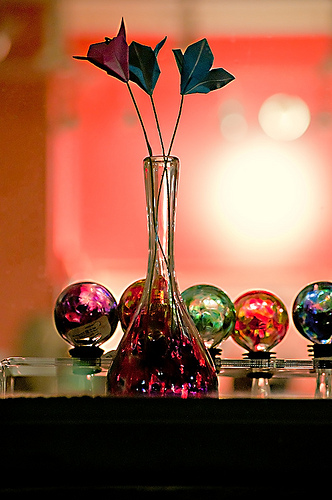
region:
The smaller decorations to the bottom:
[52, 265, 329, 352]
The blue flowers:
[136, 24, 228, 103]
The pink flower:
[73, 15, 138, 98]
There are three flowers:
[78, 14, 233, 103]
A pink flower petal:
[100, 36, 127, 81]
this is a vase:
[94, 141, 231, 411]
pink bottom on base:
[95, 305, 215, 409]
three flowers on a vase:
[60, 16, 253, 418]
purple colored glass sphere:
[46, 267, 124, 356]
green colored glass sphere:
[171, 270, 235, 362]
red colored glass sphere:
[231, 289, 291, 352]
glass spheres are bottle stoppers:
[17, 243, 330, 393]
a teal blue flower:
[163, 21, 247, 105]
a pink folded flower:
[77, 2, 136, 98]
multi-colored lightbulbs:
[51, 278, 330, 348]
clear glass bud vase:
[102, 151, 233, 391]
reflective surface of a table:
[11, 356, 331, 400]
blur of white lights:
[214, 96, 325, 265]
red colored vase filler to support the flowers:
[101, 315, 222, 389]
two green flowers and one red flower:
[68, 17, 235, 97]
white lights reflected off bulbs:
[188, 292, 331, 309]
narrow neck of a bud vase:
[139, 151, 187, 310]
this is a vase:
[75, 135, 236, 435]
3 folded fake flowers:
[68, 2, 278, 126]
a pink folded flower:
[62, 17, 136, 102]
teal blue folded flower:
[167, 23, 241, 113]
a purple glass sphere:
[38, 271, 126, 379]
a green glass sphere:
[171, 265, 244, 370]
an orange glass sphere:
[232, 280, 292, 372]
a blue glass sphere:
[280, 261, 331, 365]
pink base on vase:
[85, 271, 227, 444]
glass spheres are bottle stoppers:
[33, 263, 328, 411]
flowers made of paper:
[73, 19, 241, 138]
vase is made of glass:
[106, 141, 210, 402]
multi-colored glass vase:
[104, 154, 218, 398]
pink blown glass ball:
[53, 280, 118, 350]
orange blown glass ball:
[118, 277, 166, 336]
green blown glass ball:
[176, 283, 235, 346]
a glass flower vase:
[105, 154, 215, 393]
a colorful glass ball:
[54, 280, 117, 348]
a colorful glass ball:
[118, 277, 147, 328]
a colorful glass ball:
[180, 283, 234, 349]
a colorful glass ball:
[231, 289, 287, 353]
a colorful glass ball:
[291, 281, 330, 344]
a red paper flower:
[68, 13, 129, 81]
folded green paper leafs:
[128, 38, 167, 94]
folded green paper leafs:
[171, 37, 235, 94]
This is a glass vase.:
[90, 145, 213, 389]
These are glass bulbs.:
[53, 276, 323, 360]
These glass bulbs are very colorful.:
[41, 274, 322, 346]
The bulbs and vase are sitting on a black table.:
[43, 269, 220, 444]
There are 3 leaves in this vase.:
[81, 17, 244, 251]